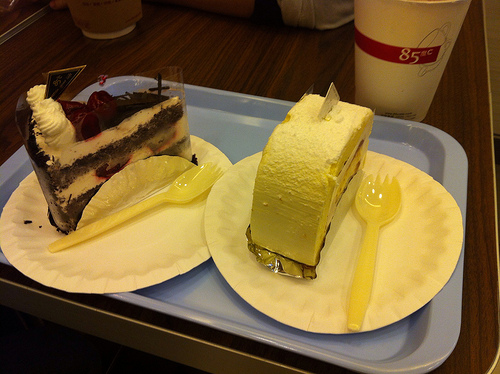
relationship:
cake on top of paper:
[17, 87, 196, 231] [75, 154, 201, 229]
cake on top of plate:
[17, 87, 196, 231] [0, 131, 234, 294]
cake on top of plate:
[251, 90, 380, 267] [204, 148, 467, 334]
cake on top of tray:
[17, 87, 196, 231] [2, 75, 469, 374]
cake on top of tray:
[251, 90, 380, 267] [2, 75, 469, 374]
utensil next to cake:
[348, 173, 399, 332] [251, 90, 380, 267]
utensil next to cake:
[46, 160, 228, 254] [17, 87, 196, 231]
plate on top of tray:
[0, 131, 234, 294] [2, 75, 469, 374]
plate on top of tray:
[204, 148, 467, 334] [2, 75, 469, 374]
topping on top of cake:
[27, 84, 75, 152] [17, 87, 196, 231]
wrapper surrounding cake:
[14, 65, 196, 236] [17, 87, 196, 231]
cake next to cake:
[17, 87, 196, 231] [251, 90, 380, 267]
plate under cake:
[0, 131, 234, 294] [17, 87, 196, 231]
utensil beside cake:
[348, 173, 399, 332] [251, 90, 380, 267]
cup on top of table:
[352, 0, 472, 122] [0, 4, 499, 374]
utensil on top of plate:
[348, 173, 399, 332] [204, 148, 467, 334]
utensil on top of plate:
[46, 160, 228, 254] [0, 131, 234, 294]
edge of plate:
[189, 134, 231, 172] [0, 131, 234, 294]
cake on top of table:
[17, 87, 196, 231] [0, 4, 499, 374]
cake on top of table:
[251, 90, 380, 267] [0, 4, 499, 374]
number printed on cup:
[398, 48, 419, 67] [352, 0, 472, 122]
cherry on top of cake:
[89, 90, 116, 117] [17, 87, 196, 231]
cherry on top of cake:
[73, 109, 102, 135] [17, 87, 196, 231]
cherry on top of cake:
[59, 100, 86, 117] [17, 87, 196, 231]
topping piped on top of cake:
[27, 84, 75, 152] [17, 87, 196, 231]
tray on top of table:
[2, 75, 469, 374] [0, 4, 499, 374]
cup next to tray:
[352, 0, 472, 122] [2, 75, 469, 374]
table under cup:
[0, 4, 499, 374] [352, 0, 472, 122]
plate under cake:
[204, 148, 467, 334] [251, 90, 380, 267]